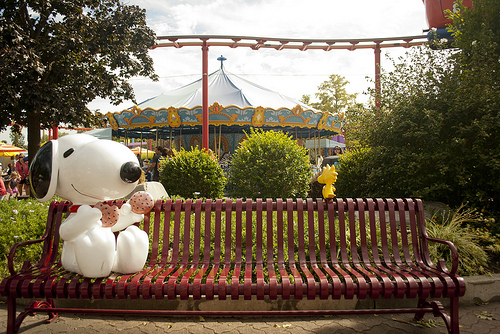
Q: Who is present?
A: No one.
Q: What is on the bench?
A: Doll.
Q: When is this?
A: Daytime.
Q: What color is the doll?
A: White.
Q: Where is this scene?
A: At a carnival.